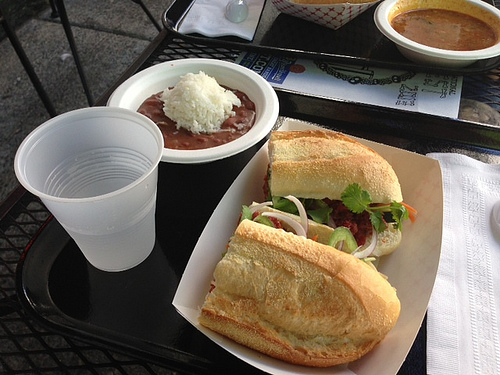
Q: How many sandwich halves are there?
A: Two.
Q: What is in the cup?
A: Water.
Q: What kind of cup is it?
A: Plastic.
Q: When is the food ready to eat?
A: Now.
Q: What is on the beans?
A: Rice.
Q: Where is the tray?
A: Table.